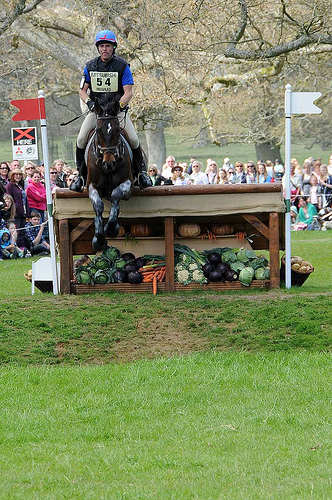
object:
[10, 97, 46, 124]
red flag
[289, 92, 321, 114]
flag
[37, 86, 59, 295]
pole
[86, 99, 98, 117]
black gloves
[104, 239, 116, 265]
vegeables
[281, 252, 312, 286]
basket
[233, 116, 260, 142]
ground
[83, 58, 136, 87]
shirt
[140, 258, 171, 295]
carrots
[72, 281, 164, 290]
container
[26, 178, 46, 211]
shirt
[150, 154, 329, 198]
people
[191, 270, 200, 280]
cauliflower head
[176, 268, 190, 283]
cauliflower head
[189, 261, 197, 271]
cauliflower head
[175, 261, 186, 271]
cauliflower head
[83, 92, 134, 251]
horse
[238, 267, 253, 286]
cabbage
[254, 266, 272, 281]
cabbage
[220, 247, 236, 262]
cabbage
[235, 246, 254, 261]
cabbage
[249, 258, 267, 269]
cabbage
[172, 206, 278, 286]
container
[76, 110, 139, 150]
pants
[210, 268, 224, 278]
vegetable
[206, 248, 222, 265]
vegetable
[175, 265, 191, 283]
vegetable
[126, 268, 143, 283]
vegetable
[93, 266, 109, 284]
vegetable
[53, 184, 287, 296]
hurdle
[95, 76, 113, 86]
number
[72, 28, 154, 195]
man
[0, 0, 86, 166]
tree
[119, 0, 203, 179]
tree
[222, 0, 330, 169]
tree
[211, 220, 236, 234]
pumpkin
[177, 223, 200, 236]
pumpkin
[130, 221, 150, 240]
pumpkin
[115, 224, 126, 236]
pumpkin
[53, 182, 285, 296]
stand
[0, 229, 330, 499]
grass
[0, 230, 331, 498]
field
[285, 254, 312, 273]
potatoes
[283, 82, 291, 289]
stand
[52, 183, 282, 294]
structure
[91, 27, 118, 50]
helmet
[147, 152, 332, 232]
crowd